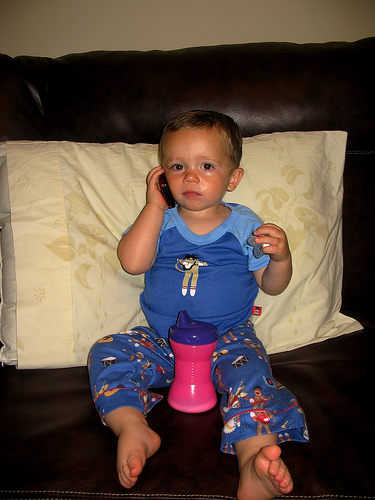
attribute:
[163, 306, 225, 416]
cup — blue , Pink 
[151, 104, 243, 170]
hair — blonde 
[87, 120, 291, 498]
boy — little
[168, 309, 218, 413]
cup — Pink , blue , purple 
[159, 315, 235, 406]
cup — Pink , blue 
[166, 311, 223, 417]
sippy cup — Pink , blue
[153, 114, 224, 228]
boy — little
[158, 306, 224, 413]
sippy cup — pink, blue